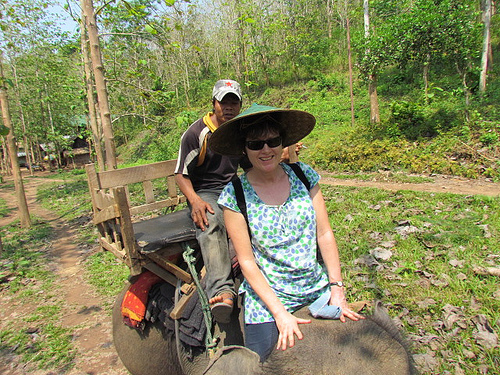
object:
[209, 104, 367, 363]
people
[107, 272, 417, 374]
elephant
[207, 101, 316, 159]
hat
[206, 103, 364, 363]
woman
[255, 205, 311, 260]
design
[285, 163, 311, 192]
straps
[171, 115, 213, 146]
shoulders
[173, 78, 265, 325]
man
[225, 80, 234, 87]
star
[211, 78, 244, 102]
cap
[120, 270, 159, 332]
blanket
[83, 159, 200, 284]
seat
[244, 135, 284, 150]
sunglasses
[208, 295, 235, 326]
sandal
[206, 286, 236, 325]
foot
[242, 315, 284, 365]
jeans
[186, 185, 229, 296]
jeans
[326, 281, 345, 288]
watch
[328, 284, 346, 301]
wrist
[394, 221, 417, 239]
leaves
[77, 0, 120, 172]
trunks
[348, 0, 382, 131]
trunks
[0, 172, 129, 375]
path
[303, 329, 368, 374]
fur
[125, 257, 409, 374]
back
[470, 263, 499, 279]
bark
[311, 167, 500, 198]
path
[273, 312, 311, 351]
hands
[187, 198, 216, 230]
hand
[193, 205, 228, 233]
knee